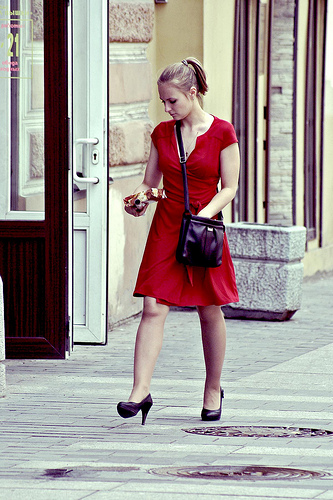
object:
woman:
[116, 57, 239, 424]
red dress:
[130, 116, 242, 309]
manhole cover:
[183, 426, 330, 439]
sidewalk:
[1, 266, 331, 498]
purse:
[176, 117, 224, 268]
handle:
[74, 138, 100, 185]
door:
[3, 3, 106, 344]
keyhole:
[89, 147, 99, 166]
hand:
[122, 194, 148, 216]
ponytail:
[184, 56, 209, 96]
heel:
[200, 387, 225, 421]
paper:
[123, 187, 168, 211]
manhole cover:
[147, 464, 329, 482]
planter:
[221, 220, 306, 325]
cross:
[183, 150, 190, 157]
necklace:
[174, 111, 211, 159]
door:
[3, 0, 69, 361]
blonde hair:
[155, 57, 209, 109]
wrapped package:
[122, 186, 167, 208]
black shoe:
[116, 393, 154, 426]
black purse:
[172, 116, 224, 267]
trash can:
[220, 219, 305, 323]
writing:
[10, 9, 34, 82]